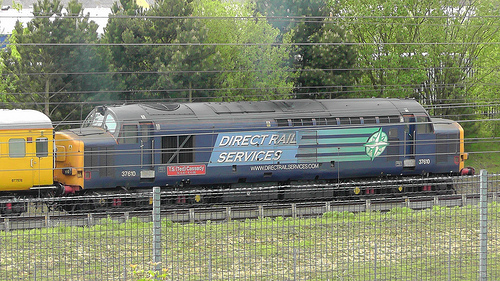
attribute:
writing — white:
[216, 135, 298, 163]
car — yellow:
[0, 105, 72, 212]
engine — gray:
[59, 103, 475, 190]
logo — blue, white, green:
[203, 124, 391, 166]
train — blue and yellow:
[0, 94, 487, 197]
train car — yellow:
[0, 104, 57, 215]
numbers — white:
[420, 159, 431, 165]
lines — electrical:
[88, 10, 478, 110]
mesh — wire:
[113, 167, 499, 263]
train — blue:
[60, 97, 472, 182]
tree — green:
[197, 4, 335, 114]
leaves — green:
[227, 36, 257, 71]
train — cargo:
[0, 88, 477, 222]